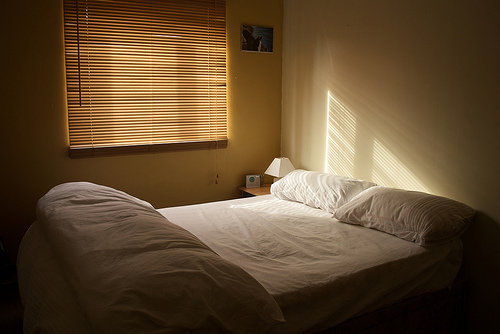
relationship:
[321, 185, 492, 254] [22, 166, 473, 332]
pillow on a bed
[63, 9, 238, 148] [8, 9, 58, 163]
window near a wall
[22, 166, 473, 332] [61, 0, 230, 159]
bed near window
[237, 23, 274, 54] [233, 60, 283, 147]
picture on wall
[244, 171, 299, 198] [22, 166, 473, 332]
table near a bed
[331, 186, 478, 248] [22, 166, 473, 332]
pillow on bed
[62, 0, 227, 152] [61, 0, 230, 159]
blinds on window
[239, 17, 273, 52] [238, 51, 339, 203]
picture on wall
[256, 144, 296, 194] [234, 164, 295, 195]
lamp on nightstand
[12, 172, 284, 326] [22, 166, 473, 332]
comforter on bed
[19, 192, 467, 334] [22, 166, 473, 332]
sheet on bed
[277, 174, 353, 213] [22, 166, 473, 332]
pillowcases on bed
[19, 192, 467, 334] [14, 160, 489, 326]
sheet on bed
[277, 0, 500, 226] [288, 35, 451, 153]
shadow on wall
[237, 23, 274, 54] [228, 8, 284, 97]
picture on wall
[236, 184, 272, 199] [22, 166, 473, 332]
table next to bed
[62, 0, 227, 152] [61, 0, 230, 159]
blinds covers window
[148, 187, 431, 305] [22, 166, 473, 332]
sheet covers bed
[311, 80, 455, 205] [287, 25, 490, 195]
shadow on wall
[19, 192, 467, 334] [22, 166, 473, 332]
sheet are on bed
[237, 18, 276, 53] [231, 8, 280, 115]
picture frame on wall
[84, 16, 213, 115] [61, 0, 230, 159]
blinds are on window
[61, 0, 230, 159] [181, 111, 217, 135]
window has shades